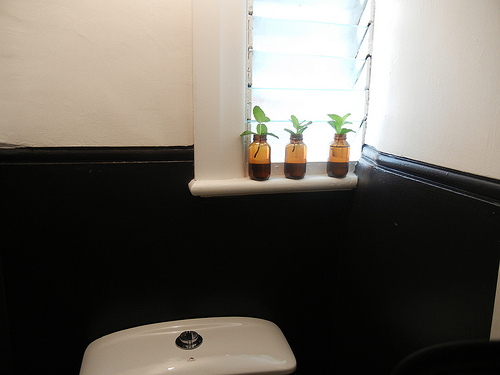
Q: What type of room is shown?
A: It is a bathroom.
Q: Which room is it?
A: It is a bathroom.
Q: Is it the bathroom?
A: Yes, it is the bathroom.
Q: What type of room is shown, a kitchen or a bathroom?
A: It is a bathroom.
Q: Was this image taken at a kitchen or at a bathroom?
A: It was taken at a bathroom.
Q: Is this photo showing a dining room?
A: No, the picture is showing a bathroom.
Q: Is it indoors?
A: Yes, it is indoors.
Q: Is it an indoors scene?
A: Yes, it is indoors.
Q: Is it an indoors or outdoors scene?
A: It is indoors.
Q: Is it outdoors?
A: No, it is indoors.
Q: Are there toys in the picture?
A: No, there are no toys.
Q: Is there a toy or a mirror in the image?
A: No, there are no toys or mirrors.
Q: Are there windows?
A: Yes, there is a window.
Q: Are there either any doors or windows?
A: Yes, there is a window.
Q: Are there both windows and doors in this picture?
A: No, there is a window but no doors.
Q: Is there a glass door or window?
A: Yes, there is a glass window.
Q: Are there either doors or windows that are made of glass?
A: Yes, the window is made of glass.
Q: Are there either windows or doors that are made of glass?
A: Yes, the window is made of glass.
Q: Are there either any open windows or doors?
A: Yes, there is an open window.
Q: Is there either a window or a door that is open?
A: Yes, the window is open.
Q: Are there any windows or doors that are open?
A: Yes, the window is open.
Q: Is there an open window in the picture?
A: Yes, there is an open window.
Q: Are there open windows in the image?
A: Yes, there is an open window.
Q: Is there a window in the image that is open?
A: Yes, there is a window that is open.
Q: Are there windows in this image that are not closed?
A: Yes, there is a open window.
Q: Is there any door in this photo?
A: No, there are no doors.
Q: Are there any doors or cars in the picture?
A: No, there are no doors or cars.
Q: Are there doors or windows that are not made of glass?
A: No, there is a window but it is made of glass.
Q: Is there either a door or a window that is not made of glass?
A: No, there is a window but it is made of glass.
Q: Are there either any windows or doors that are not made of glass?
A: No, there is a window but it is made of glass.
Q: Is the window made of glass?
A: Yes, the window is made of glass.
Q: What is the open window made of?
A: The window is made of glass.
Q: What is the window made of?
A: The window is made of glass.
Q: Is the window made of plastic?
A: No, the window is made of glass.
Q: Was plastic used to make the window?
A: No, the window is made of glass.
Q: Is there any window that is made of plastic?
A: No, there is a window but it is made of glass.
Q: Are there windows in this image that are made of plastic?
A: No, there is a window but it is made of glass.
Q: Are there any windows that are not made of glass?
A: No, there is a window but it is made of glass.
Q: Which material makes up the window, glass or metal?
A: The window is made of glass.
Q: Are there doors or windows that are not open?
A: No, there is a window but it is open.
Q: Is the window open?
A: Yes, the window is open.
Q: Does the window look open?
A: Yes, the window is open.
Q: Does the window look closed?
A: No, the window is open.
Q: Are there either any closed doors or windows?
A: No, there is a window but it is open.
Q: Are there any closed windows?
A: No, there is a window but it is open.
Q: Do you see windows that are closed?
A: No, there is a window but it is open.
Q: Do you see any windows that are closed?
A: No, there is a window but it is open.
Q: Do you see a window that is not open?
A: No, there is a window but it is open.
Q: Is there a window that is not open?
A: No, there is a window but it is open.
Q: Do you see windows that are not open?
A: No, there is a window but it is open.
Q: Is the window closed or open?
A: The window is open.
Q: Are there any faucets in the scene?
A: No, there are no faucets.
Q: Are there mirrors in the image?
A: No, there are no mirrors.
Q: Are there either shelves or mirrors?
A: No, there are no mirrors or shelves.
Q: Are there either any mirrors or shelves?
A: No, there are no mirrors or shelves.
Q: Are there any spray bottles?
A: No, there are no spray bottles.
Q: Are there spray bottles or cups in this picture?
A: No, there are no spray bottles or cups.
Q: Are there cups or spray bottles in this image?
A: No, there are no spray bottles or cups.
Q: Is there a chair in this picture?
A: No, there are no chairs.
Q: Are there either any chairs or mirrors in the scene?
A: No, there are no chairs or mirrors.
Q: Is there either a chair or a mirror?
A: No, there are no chairs or mirrors.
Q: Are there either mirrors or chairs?
A: No, there are no chairs or mirrors.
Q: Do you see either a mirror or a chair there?
A: No, there are no chairs or mirrors.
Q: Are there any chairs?
A: No, there are no chairs.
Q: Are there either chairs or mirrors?
A: No, there are no chairs or mirrors.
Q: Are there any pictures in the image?
A: No, there are no pictures.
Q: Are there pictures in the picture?
A: No, there are no pictures.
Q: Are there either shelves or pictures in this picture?
A: No, there are no pictures or shelves.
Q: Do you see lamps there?
A: No, there are no lamps.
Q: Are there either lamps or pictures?
A: No, there are no lamps or pictures.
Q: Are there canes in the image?
A: No, there are no canes.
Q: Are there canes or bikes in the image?
A: No, there are no canes or bikes.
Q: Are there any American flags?
A: No, there are no American flags.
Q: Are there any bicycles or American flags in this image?
A: No, there are no American flags or bicycles.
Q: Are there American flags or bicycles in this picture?
A: No, there are no American flags or bicycles.